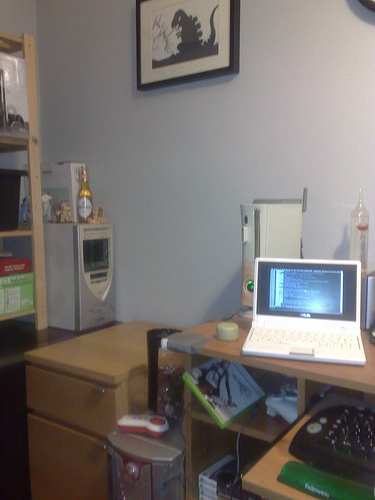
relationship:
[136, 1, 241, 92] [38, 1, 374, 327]
picture hanging on wall